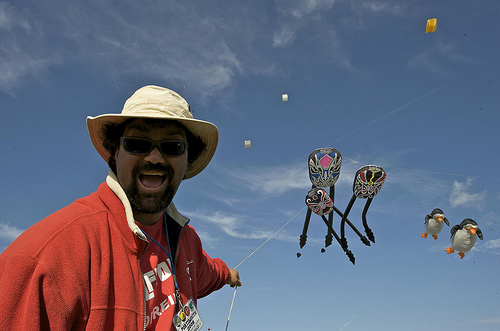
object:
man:
[0, 84, 242, 331]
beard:
[117, 164, 176, 215]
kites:
[304, 187, 370, 268]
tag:
[171, 299, 203, 331]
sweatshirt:
[0, 169, 229, 331]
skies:
[75, 11, 337, 97]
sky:
[219, 16, 417, 117]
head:
[106, 98, 194, 214]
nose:
[143, 145, 166, 165]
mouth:
[134, 165, 174, 192]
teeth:
[141, 170, 166, 176]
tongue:
[142, 176, 163, 189]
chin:
[127, 197, 170, 213]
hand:
[226, 269, 242, 288]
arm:
[185, 245, 230, 290]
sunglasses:
[117, 136, 193, 157]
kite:
[340, 164, 386, 249]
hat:
[85, 84, 218, 180]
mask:
[357, 165, 384, 185]